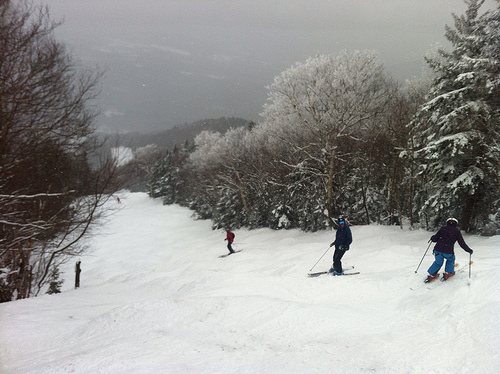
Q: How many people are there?
A: 3.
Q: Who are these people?
A: Skiers.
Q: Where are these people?
A: In the snow.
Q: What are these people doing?
A: Skiing.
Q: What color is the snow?
A: White.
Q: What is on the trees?
A: Snow.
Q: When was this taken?
A: Daytime.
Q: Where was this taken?
A: In the mountains.